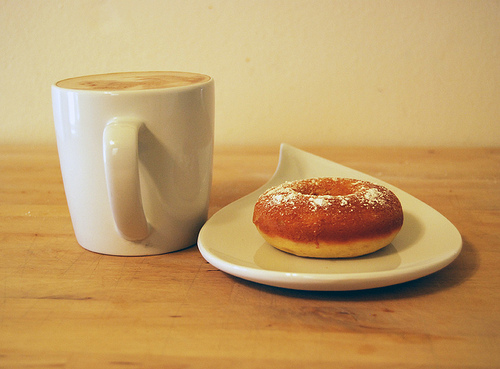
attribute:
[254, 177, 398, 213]
sugar — white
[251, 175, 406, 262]
doughnut — brown, round, beige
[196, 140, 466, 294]
plate — white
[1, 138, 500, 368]
table — surface, wooden, brown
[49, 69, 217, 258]
mug — white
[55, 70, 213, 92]
liquid — brown, tan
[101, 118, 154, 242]
handle — white, curved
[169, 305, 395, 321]
spots — dark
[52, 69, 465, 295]
cup and plate — white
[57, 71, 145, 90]
cream — white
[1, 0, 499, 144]
wall — white